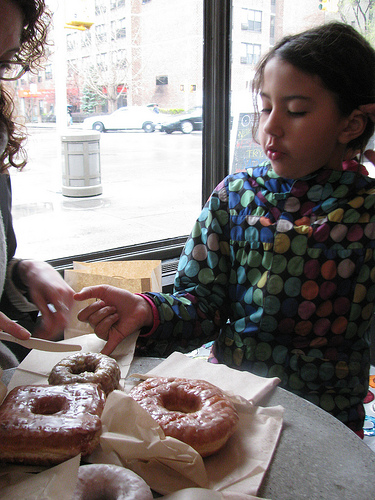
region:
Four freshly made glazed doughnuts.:
[7, 294, 264, 496]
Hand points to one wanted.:
[51, 281, 157, 384]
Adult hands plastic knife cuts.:
[2, 244, 86, 384]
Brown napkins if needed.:
[132, 345, 287, 492]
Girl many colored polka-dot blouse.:
[105, 102, 356, 353]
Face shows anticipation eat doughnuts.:
[253, 49, 343, 184]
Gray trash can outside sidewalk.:
[38, 121, 124, 208]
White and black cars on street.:
[85, 97, 208, 136]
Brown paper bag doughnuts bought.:
[48, 253, 176, 348]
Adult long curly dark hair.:
[3, 2, 41, 187]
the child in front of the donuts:
[72, 20, 374, 440]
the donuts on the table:
[0, 351, 238, 498]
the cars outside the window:
[83, 104, 202, 133]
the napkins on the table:
[0, 332, 284, 498]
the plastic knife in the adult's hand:
[0, 330, 82, 351]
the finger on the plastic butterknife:
[0, 310, 30, 339]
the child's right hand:
[73, 284, 144, 355]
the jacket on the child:
[143, 158, 373, 431]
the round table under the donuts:
[0, 355, 374, 499]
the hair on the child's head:
[250, 21, 373, 175]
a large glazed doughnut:
[121, 375, 239, 459]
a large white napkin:
[130, 350, 281, 401]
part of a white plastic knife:
[0, 329, 84, 359]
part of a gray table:
[136, 355, 372, 498]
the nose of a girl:
[257, 107, 283, 138]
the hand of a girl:
[74, 284, 151, 356]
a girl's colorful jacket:
[142, 160, 374, 429]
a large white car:
[83, 104, 168, 131]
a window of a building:
[111, 19, 126, 37]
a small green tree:
[74, 81, 101, 117]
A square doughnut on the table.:
[0, 380, 106, 450]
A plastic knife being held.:
[2, 328, 82, 353]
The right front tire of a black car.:
[180, 120, 193, 132]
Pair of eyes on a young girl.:
[259, 97, 308, 117]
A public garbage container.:
[56, 127, 105, 197]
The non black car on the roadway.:
[79, 102, 173, 135]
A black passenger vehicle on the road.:
[154, 110, 237, 133]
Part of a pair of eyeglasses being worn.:
[0, 48, 31, 87]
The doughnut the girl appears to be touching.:
[47, 348, 122, 391]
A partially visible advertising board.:
[231, 106, 268, 176]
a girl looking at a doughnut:
[69, 12, 370, 462]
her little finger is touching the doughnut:
[62, 275, 148, 358]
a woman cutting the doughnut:
[1, 5, 90, 352]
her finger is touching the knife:
[0, 322, 90, 353]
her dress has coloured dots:
[143, 159, 370, 460]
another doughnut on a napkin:
[102, 366, 285, 496]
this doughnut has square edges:
[2, 379, 106, 457]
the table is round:
[1, 341, 363, 494]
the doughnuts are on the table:
[0, 350, 374, 493]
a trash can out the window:
[53, 121, 115, 213]